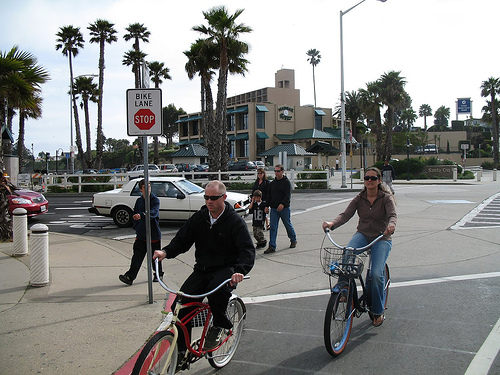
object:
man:
[152, 180, 256, 373]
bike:
[130, 257, 252, 373]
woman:
[320, 166, 397, 327]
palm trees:
[476, 75, 500, 175]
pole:
[140, 136, 153, 305]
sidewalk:
[0, 228, 196, 374]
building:
[170, 62, 494, 169]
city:
[0, 0, 500, 374]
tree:
[86, 19, 121, 172]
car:
[90, 176, 254, 229]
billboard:
[453, 98, 473, 119]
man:
[116, 177, 163, 286]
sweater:
[131, 192, 161, 241]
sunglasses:
[363, 175, 382, 181]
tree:
[334, 69, 417, 167]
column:
[27, 222, 51, 286]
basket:
[320, 247, 365, 277]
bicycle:
[320, 223, 390, 356]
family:
[243, 163, 297, 254]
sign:
[125, 87, 165, 135]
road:
[0, 168, 499, 373]